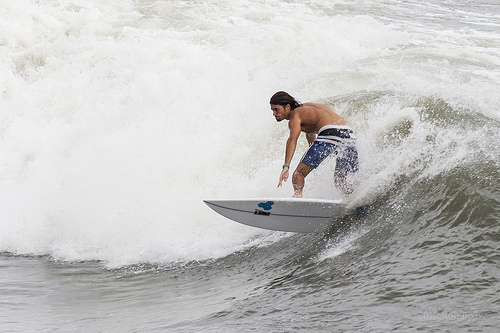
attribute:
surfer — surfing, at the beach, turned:
[271, 90, 360, 199]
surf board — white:
[202, 198, 357, 235]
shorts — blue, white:
[301, 122, 360, 173]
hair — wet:
[272, 92, 303, 110]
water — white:
[7, 7, 496, 329]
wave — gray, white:
[287, 92, 500, 269]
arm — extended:
[279, 117, 303, 168]